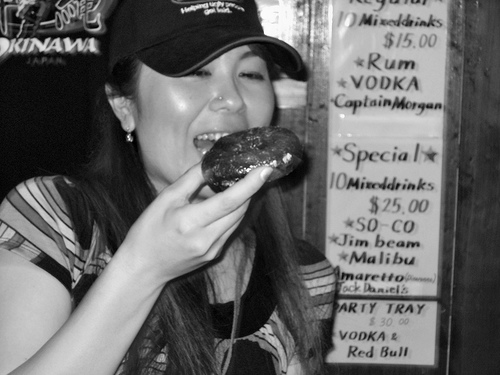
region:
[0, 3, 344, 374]
woman eating a doughnut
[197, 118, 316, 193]
doughnut in woman's hand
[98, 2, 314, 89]
baseball cap on a woman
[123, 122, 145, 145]
earring on woman's right ear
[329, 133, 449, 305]
special menu signs on wall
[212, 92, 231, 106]
nose ring on woman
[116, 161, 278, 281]
right hand holding doughnut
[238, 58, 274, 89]
left eye of woman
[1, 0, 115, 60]
bar sign behind woman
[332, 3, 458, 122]
drink sign on wall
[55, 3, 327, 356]
woman with donut in hand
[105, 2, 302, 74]
hat with words on front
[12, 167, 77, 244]
sleeve of striped shirt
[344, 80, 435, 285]
handwritten words on sign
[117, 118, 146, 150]
earring in ear lobe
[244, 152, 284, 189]
index finger on donut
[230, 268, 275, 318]
solid collar of shirt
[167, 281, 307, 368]
long hair covering shirt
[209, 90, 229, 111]
jewelry in woman's nose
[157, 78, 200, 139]
light reflection on cheek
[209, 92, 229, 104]
The earring in the girl's nose.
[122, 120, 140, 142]
The earring in the girl's ear.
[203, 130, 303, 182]
The doughnut the girl is getting ready to bite.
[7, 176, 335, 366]
The striped shirt the girl is wearing.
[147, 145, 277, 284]
The hand of the girl.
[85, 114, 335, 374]
The girl's hair draped over her shoulders.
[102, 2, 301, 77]
The black hat the girl is wearing.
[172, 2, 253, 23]
The white letters on the girl's hat.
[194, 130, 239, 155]
The teeth of the girl eating the doughnut.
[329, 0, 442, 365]
The white sign taped to the wall with items and prices written on it.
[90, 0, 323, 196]
The woman is wearing a hat.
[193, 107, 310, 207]
The woman is holding a donut.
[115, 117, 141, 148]
An earring on the woman's ear.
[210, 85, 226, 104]
The woman has a nose ring.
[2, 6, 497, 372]
Black and white photograph of a woman.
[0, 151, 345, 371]
The woman is waring a striped shirt.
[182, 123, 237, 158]
The woman's teeth are visible.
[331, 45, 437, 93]
The sign says rum and vodka.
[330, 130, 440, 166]
The sign says special.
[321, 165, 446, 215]
The sign offers 10 mixed drinks for $25.00.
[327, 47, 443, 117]
List of drinks on board.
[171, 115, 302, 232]
A doughnut in hand.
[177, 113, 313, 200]
A women about to eat.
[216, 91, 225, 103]
Jewelery in the nose.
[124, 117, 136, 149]
earing hangs down from ear.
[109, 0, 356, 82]
A women wears hat.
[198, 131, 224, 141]
The womens teeth.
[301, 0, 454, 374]
Sign on the wall.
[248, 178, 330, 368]
Her hair hanging down.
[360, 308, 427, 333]
The price of the party tray.